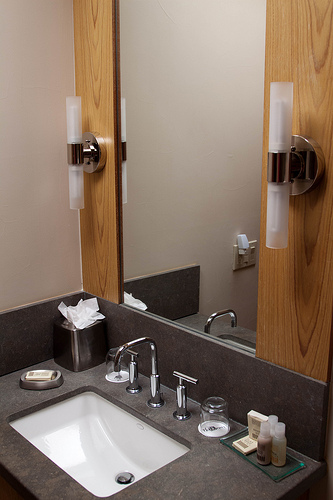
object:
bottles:
[255, 412, 288, 467]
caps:
[260, 413, 286, 434]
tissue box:
[53, 316, 108, 373]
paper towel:
[56, 296, 106, 332]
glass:
[198, 396, 231, 439]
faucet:
[113, 335, 162, 404]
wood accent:
[73, 1, 123, 304]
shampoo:
[271, 422, 288, 468]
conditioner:
[256, 421, 272, 465]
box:
[52, 317, 110, 374]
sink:
[10, 385, 191, 498]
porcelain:
[103, 417, 126, 465]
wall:
[117, 0, 267, 331]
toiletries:
[254, 413, 287, 467]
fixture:
[172, 369, 200, 421]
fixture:
[124, 348, 142, 394]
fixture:
[113, 336, 164, 409]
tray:
[218, 425, 308, 484]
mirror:
[114, 0, 268, 359]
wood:
[275, 253, 327, 362]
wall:
[1, 6, 64, 284]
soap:
[24, 369, 55, 381]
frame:
[110, 0, 126, 303]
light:
[237, 233, 250, 255]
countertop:
[0, 359, 326, 500]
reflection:
[70, 329, 92, 373]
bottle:
[197, 395, 231, 439]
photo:
[0, 0, 333, 499]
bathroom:
[0, 0, 333, 500]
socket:
[232, 240, 257, 271]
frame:
[255, 0, 270, 357]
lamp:
[265, 80, 294, 251]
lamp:
[65, 95, 85, 212]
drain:
[114, 471, 135, 485]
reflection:
[56, 425, 88, 466]